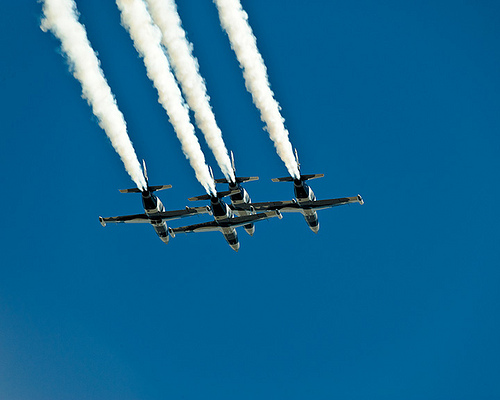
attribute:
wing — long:
[165, 204, 211, 219]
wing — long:
[98, 212, 148, 227]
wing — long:
[240, 199, 296, 214]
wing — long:
[232, 210, 284, 229]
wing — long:
[313, 194, 363, 214]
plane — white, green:
[263, 170, 367, 239]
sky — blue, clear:
[31, 244, 458, 377]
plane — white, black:
[98, 184, 202, 250]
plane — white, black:
[174, 189, 284, 251]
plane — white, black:
[210, 177, 296, 237]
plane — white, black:
[262, 172, 365, 231]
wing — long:
[231, 205, 287, 232]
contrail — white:
[213, 0, 302, 179]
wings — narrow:
[95, 202, 214, 230]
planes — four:
[94, 166, 369, 248]